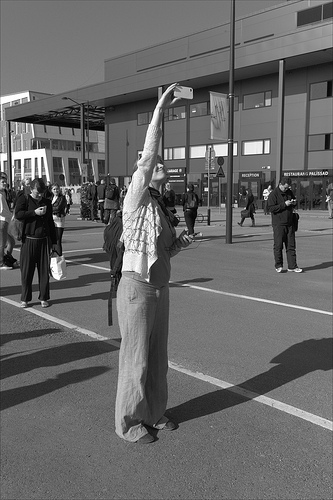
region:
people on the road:
[47, 67, 291, 411]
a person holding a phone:
[83, 60, 250, 383]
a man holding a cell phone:
[90, 64, 231, 323]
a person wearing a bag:
[22, 158, 64, 327]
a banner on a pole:
[185, 55, 284, 262]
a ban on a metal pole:
[197, 73, 264, 210]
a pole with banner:
[192, 51, 280, 250]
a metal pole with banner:
[174, 51, 245, 252]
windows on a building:
[109, 72, 299, 207]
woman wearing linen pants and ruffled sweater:
[102, 132, 212, 477]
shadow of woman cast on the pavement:
[176, 332, 332, 430]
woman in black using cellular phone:
[9, 172, 71, 324]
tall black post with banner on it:
[201, 0, 243, 250]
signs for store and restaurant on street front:
[235, 164, 331, 183]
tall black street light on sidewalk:
[55, 90, 87, 198]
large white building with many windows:
[4, 86, 104, 200]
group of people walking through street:
[69, 167, 118, 214]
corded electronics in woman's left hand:
[166, 221, 206, 263]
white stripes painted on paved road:
[194, 271, 315, 444]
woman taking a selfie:
[98, 72, 201, 449]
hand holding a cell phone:
[151, 77, 200, 114]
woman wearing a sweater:
[114, 75, 207, 280]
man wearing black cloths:
[264, 173, 308, 276]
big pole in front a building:
[223, 5, 240, 246]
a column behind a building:
[76, 101, 90, 186]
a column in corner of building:
[2, 116, 18, 184]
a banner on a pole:
[204, 87, 241, 149]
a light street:
[58, 88, 89, 168]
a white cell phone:
[170, 80, 195, 101]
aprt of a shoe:
[139, 424, 155, 452]